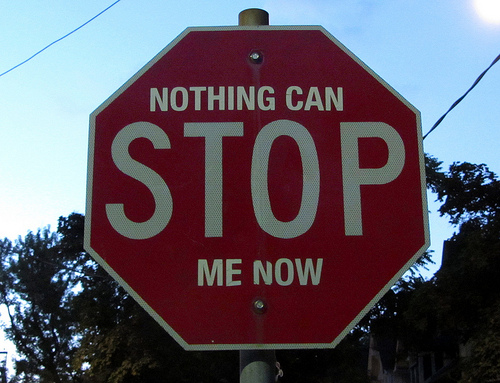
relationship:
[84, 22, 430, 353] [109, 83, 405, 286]
sign has lettering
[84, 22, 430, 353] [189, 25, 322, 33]
sign has edge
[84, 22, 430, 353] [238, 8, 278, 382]
sign affixed to pole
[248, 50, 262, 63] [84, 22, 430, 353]
bolt attached to sign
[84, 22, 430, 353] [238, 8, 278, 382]
sign attached to pole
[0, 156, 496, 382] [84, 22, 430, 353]
trees are behind sign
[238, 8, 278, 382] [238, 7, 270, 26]
pole has top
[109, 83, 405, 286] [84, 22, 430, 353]
lettering on front of sign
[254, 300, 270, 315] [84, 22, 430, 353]
bolt attached to sign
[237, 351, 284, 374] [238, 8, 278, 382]
shadow on pole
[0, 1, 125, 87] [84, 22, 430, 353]
power line behind sign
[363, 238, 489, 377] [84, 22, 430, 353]
house to right of sign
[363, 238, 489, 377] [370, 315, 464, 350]
house has roof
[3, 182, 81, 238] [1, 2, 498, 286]
clouds are floating in sky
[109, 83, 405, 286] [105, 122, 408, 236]
lettering reads stop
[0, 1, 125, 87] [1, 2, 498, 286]
power line in front of sky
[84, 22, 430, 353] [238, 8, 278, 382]
sign on pole